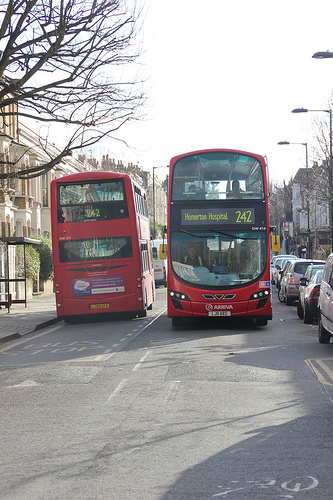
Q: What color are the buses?
A: Red.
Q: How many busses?
A: Two.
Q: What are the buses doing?
A: Driving.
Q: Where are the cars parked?
A: On the road.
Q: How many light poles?
A: Three.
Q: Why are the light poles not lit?
A: It's daytime.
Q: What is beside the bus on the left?
A: Bus stop.